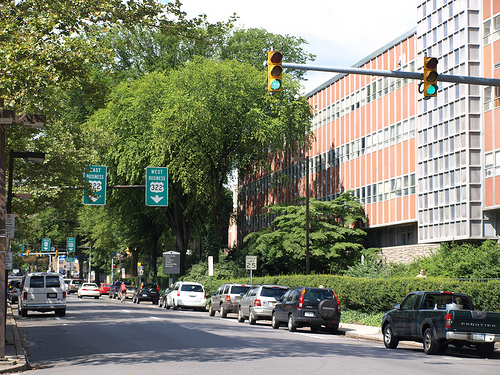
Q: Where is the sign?
A: On pole.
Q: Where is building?
A: Side of road.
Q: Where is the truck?
A: On street.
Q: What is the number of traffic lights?
A: 2.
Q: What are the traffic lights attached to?
A: Pole.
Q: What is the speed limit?
A: 25 mph.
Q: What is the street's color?
A: Grey.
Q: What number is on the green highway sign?
A: 322.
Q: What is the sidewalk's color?
A: White.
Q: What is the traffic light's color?
A: Green.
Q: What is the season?
A: Summer.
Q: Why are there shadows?
A: Sunny.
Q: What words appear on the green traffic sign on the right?
A: West Business.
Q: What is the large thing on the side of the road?
A: Building.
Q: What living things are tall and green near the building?
A: Trees.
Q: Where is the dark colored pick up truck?
A: Parked under the traffic light.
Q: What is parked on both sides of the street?
A: Vehicles.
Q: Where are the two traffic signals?
A: Hanging off the pole on the right.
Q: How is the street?
A: Busy.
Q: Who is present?
A: Cyclist.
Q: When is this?
A: Daytime.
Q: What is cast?
A: Shadows.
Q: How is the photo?
A: Clear.